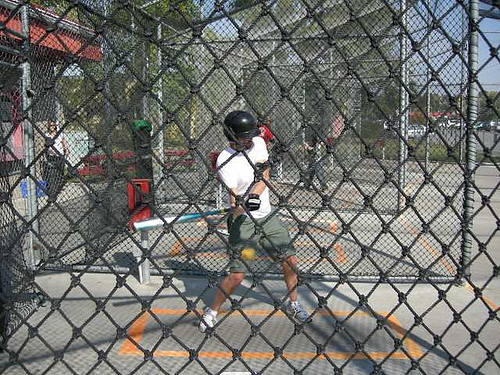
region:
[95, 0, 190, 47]
a bunch of trees behind the fence.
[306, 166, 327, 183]
a man is wearing black jean pants.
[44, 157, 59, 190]
a woman is wearing black pants.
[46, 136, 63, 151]
a woman is wearing a grey shirt.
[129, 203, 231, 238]
a man is swinging a grey and blue bat.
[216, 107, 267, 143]
a man is wearing a black helmet.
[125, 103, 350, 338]
a man is behind a fence playing base ball.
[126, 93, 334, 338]
a man swinging a bat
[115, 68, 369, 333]
a man in a batter's cage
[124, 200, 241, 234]
a blue and silver aluminum bat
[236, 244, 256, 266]
a yellow ball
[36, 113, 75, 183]
a woman walking behind a fence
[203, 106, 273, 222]
a man wearing a t-shirt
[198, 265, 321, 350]
the legs of a man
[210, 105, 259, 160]
a man wearing a batter's helmet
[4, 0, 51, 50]
piece of black fence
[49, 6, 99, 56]
piece of black fence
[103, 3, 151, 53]
piece of black fence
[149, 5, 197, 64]
piece of black fence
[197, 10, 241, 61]
piece of black fence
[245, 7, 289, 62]
piece of black fence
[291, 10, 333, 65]
piece of black fence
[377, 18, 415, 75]
piece of black fence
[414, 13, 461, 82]
piece of black fence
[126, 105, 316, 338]
guy swinging a bat at the batting cages.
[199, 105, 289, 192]
man has a black helmet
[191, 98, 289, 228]
man wears a white shirt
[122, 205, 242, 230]
bat is color white and blue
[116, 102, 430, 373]
baseball player is on a home base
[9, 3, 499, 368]
a baseball field is fenced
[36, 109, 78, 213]
a woman behind a fence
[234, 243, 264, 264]
a ball color yellow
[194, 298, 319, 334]
a pair of white shoes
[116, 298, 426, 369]
an orange square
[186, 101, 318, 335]
batter standing in box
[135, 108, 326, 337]
man holding a bat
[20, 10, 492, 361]
a row of batting cages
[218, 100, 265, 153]
man wearing a black helmet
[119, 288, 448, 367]
orange box on the ground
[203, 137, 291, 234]
man wearing a white shirt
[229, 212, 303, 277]
green pair of shorts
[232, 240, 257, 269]
ball is in motion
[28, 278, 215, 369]
shadows on the ground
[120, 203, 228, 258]
silver and blue bat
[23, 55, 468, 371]
a scene during the day time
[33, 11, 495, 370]
a scene of a batting cage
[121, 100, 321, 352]
a person swinging a bat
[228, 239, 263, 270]
a yellow ball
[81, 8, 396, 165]
some green trees in the background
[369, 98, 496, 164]
cars in the parking lot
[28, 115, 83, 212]
a person on the left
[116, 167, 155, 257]
a red box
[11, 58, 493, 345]
a black fence in the forefront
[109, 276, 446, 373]
a yellow rectangle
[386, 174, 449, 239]
the fence is chain link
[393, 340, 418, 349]
the stripe is yellow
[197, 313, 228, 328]
foot of the boy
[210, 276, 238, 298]
leg of the boy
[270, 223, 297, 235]
the shorts are green